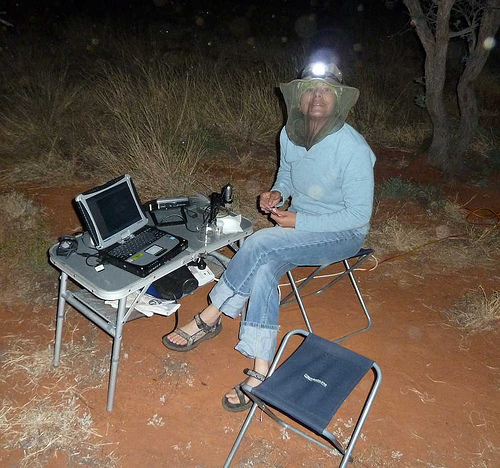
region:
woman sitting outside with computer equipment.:
[19, 10, 466, 436]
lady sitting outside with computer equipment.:
[16, 36, 471, 437]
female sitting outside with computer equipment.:
[53, 16, 438, 433]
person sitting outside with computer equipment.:
[27, 19, 431, 428]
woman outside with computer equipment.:
[11, 25, 452, 430]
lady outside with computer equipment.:
[20, 32, 432, 424]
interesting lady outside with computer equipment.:
[12, 36, 441, 435]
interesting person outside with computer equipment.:
[32, 8, 419, 425]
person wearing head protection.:
[265, 50, 365, 153]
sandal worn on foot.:
[159, 302, 221, 357]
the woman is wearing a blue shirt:
[265, 123, 385, 229]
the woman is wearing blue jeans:
[211, 221, 374, 359]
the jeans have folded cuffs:
[206, 271, 282, 361]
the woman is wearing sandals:
[164, 310, 276, 415]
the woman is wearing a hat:
[284, 60, 350, 94]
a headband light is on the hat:
[303, 61, 340, 86]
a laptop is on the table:
[78, 173, 188, 270]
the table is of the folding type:
[46, 189, 251, 414]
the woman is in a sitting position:
[163, 51, 378, 409]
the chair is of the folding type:
[275, 237, 375, 347]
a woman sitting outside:
[215, 50, 404, 392]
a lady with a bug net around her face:
[269, 47, 364, 157]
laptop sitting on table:
[53, 172, 188, 279]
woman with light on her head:
[285, 42, 357, 122]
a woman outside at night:
[12, 38, 413, 464]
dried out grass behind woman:
[30, 50, 380, 177]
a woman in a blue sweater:
[253, 45, 379, 235]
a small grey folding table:
[47, 187, 256, 410]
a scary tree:
[403, 11, 497, 181]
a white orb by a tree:
[441, 15, 498, 85]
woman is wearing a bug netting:
[269, 62, 414, 168]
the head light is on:
[276, 44, 370, 104]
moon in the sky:
[467, 20, 498, 64]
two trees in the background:
[410, 16, 497, 173]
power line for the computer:
[170, 253, 407, 285]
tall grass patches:
[50, 66, 254, 176]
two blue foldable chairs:
[297, 236, 379, 448]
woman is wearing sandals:
[173, 317, 286, 409]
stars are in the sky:
[124, 16, 377, 69]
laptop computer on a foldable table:
[76, 179, 175, 269]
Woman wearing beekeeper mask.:
[246, 53, 398, 203]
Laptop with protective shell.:
[31, 165, 185, 290]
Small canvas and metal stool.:
[213, 323, 408, 450]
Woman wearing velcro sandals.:
[188, 52, 380, 413]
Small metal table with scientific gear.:
[31, 175, 250, 411]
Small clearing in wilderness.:
[5, 102, 498, 458]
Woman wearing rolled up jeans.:
[167, 63, 379, 390]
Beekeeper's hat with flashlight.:
[248, 52, 370, 107]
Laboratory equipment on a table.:
[48, 167, 270, 404]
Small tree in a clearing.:
[386, 2, 498, 191]